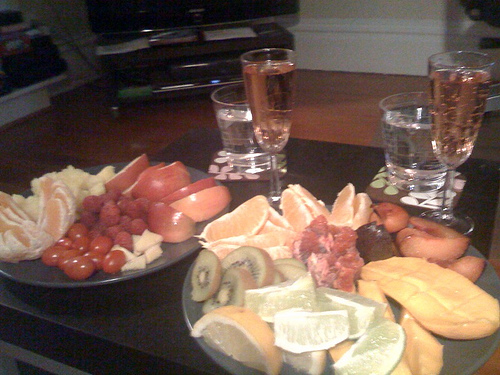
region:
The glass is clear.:
[213, 75, 288, 177]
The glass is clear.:
[231, 36, 308, 228]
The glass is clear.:
[377, 73, 457, 202]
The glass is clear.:
[418, 39, 487, 248]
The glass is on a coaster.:
[193, 75, 295, 195]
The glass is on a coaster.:
[360, 85, 475, 216]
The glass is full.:
[418, 40, 498, 243]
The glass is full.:
[373, 86, 460, 195]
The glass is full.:
[238, 38, 312, 223]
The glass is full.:
[207, 75, 299, 178]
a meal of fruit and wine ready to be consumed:
[1, 38, 498, 373]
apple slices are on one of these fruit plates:
[105, 150, 229, 242]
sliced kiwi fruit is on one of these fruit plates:
[185, 239, 280, 311]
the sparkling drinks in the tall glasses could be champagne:
[234, 38, 498, 183]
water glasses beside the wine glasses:
[202, 75, 453, 190]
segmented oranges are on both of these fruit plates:
[0, 172, 376, 267]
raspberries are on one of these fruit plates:
[75, 190, 150, 245]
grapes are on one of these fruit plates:
[37, 210, 123, 276]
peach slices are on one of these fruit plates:
[397, 212, 487, 283]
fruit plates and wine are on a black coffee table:
[3, 119, 499, 372]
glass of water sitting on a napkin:
[377, 93, 443, 196]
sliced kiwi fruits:
[189, 250, 269, 307]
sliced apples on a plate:
[116, 160, 223, 222]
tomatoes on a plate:
[50, 226, 120, 279]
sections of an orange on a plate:
[0, 180, 64, 255]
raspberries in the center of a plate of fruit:
[86, 193, 137, 233]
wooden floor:
[301, 73, 371, 135]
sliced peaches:
[395, 222, 478, 266]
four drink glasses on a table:
[208, 33, 495, 210]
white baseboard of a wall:
[302, 15, 427, 77]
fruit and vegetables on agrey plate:
[0, 160, 231, 288]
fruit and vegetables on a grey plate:
[180, 181, 495, 367]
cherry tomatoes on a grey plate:
[40, 220, 120, 275]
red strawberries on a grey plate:
[77, 190, 142, 250]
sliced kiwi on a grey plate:
[190, 245, 271, 315]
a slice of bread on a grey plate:
[360, 257, 497, 342]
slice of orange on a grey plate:
[203, 195, 269, 239]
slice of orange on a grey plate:
[190, 304, 280, 373]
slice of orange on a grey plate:
[282, 187, 329, 239]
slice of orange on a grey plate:
[330, 184, 372, 229]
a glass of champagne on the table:
[238, 48, 299, 209]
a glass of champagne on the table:
[425, 54, 492, 235]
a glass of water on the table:
[377, 92, 454, 199]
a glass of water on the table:
[210, 82, 287, 175]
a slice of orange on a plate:
[190, 307, 283, 374]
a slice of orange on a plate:
[202, 194, 267, 244]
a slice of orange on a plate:
[279, 185, 327, 235]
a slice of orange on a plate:
[333, 184, 370, 227]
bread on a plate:
[361, 258, 498, 338]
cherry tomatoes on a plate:
[40, 221, 125, 281]